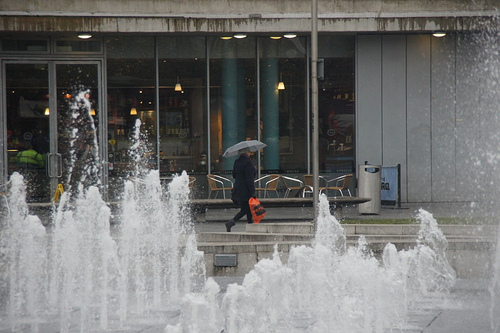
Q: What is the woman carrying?
A: An orange bag and an umbrella.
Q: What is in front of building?
A: Water fountain.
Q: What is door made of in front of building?
A: Glass.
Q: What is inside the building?
A: Lamps.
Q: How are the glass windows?
A: Large and tall.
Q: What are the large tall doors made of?
A: Glass.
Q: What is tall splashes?
A: Water.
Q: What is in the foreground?
A: Water.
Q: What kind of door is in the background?
A: Glass.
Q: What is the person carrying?
A: An umbrella.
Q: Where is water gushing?
A: From fountain.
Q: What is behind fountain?
A: Building with windows and doors.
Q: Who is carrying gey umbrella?
A: Woman walking.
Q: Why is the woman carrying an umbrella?
A: It is raining.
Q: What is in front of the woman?
A: A water feature.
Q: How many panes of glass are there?
A: Seven.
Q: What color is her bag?
A: Red.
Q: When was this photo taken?
A: During the day.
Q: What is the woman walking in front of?
A: A building.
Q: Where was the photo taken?
A: In a city.